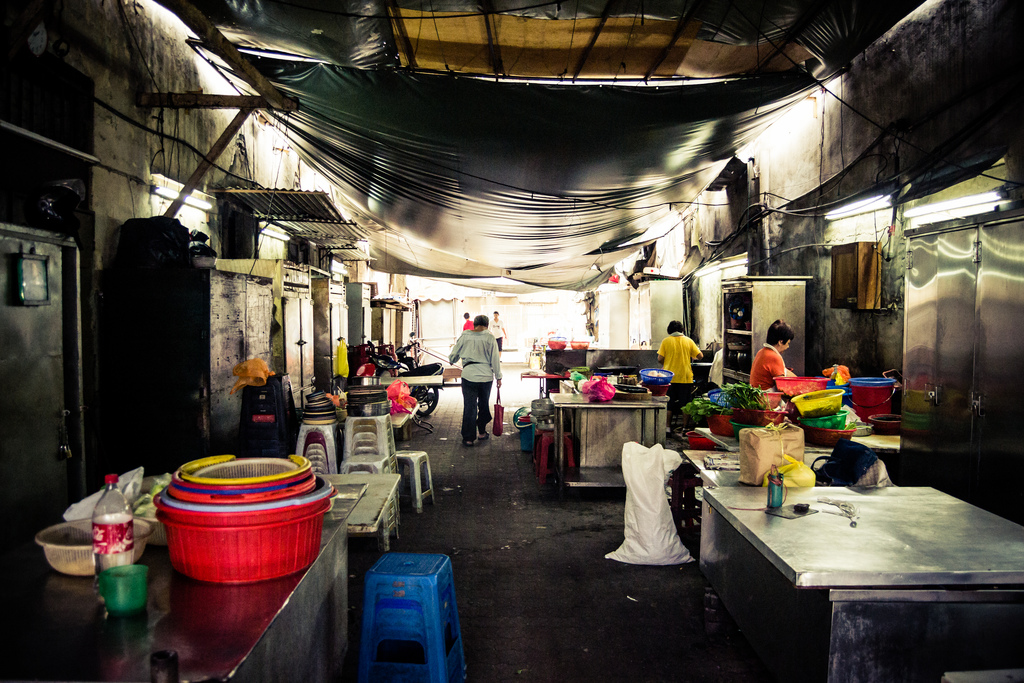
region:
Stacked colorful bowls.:
[162, 438, 324, 576]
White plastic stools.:
[291, 400, 428, 508]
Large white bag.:
[607, 434, 688, 561]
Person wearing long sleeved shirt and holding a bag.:
[446, 314, 504, 439]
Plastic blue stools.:
[362, 547, 454, 680]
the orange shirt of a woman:
[750, 346, 779, 385]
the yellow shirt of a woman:
[645, 331, 710, 383]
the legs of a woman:
[453, 372, 495, 433]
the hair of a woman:
[653, 314, 688, 353]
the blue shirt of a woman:
[438, 333, 522, 388]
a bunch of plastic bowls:
[136, 459, 320, 589]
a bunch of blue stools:
[346, 540, 479, 668]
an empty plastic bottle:
[92, 463, 153, 568]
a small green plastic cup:
[93, 567, 157, 612]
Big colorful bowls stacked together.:
[150, 447, 334, 578]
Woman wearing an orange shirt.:
[747, 314, 804, 397]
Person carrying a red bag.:
[447, 305, 505, 441]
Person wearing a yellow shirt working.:
[649, 311, 700, 403]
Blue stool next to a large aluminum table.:
[343, 548, 474, 676]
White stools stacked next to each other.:
[289, 409, 436, 509]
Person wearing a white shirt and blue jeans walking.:
[453, 308, 505, 442]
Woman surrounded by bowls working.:
[747, 314, 804, 404]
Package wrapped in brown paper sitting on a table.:
[722, 419, 805, 484]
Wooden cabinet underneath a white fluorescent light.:
[825, 239, 884, 312]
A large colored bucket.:
[147, 443, 348, 576]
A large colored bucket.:
[154, 475, 344, 502]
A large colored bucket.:
[171, 475, 340, 498]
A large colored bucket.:
[166, 456, 326, 489]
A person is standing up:
[648, 305, 705, 419]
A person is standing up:
[445, 315, 500, 439]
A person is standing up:
[487, 310, 507, 350]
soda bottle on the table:
[88, 462, 136, 593]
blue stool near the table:
[351, 531, 465, 680]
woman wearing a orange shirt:
[745, 328, 784, 385]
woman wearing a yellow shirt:
[650, 329, 702, 383]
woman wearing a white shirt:
[449, 320, 506, 393]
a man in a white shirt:
[468, 318, 503, 421]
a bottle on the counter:
[94, 477, 139, 572]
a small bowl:
[34, 527, 161, 573]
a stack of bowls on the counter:
[161, 451, 340, 576]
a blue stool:
[363, 552, 453, 658]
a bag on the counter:
[739, 424, 796, 475]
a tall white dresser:
[718, 277, 791, 379]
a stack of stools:
[294, 399, 419, 476]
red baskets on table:
[106, 408, 366, 602]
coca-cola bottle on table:
[54, 457, 187, 617]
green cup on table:
[62, 555, 186, 639]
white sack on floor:
[585, 418, 719, 612]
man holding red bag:
[421, 289, 542, 477]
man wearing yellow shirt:
[611, 308, 719, 458]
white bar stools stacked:
[280, 394, 454, 494]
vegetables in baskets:
[681, 370, 811, 441]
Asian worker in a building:
[651, 313, 703, 409]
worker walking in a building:
[441, 309, 505, 442]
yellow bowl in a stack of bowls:
[172, 448, 312, 488]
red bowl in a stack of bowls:
[169, 476, 322, 495]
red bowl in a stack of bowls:
[150, 508, 334, 588]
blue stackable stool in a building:
[349, 541, 464, 679]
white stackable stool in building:
[392, 441, 441, 514]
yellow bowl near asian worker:
[779, 382, 849, 417]